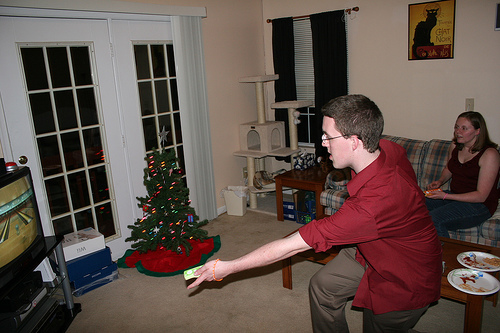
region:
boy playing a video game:
[164, 85, 441, 327]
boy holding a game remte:
[158, 214, 345, 296]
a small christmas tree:
[102, 117, 241, 255]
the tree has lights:
[129, 139, 201, 247]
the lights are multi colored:
[102, 117, 214, 252]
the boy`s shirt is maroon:
[265, 133, 440, 326]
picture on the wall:
[377, 1, 466, 70]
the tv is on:
[2, 166, 97, 308]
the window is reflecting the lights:
[56, 125, 123, 230]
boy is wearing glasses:
[300, 110, 353, 146]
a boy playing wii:
[181, 95, 432, 332]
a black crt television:
[1, 165, 46, 282]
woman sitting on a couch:
[425, 110, 498, 240]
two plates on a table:
[448, 248, 499, 295]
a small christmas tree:
[128, 127, 205, 262]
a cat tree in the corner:
[228, 70, 303, 217]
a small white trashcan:
[223, 183, 249, 215]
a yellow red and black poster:
[405, 0, 455, 61]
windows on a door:
[15, 39, 123, 244]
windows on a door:
[132, 43, 189, 194]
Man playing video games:
[185, 92, 442, 330]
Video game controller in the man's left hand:
[182, 264, 205, 281]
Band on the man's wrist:
[211, 257, 225, 282]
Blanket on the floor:
[118, 228, 220, 276]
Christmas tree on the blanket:
[125, 123, 210, 254]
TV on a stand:
[1, 167, 45, 294]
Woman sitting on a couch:
[422, 109, 499, 240]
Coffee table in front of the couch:
[281, 225, 496, 331]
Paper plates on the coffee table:
[446, 250, 499, 295]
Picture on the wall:
[407, 0, 454, 60]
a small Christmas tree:
[128, 128, 211, 258]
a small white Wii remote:
[179, 260, 223, 286]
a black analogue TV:
[0, 144, 53, 292]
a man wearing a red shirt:
[283, 91, 448, 312]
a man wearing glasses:
[317, 87, 387, 197]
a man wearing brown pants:
[292, 82, 455, 329]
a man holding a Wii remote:
[155, 65, 415, 307]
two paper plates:
[450, 242, 497, 310]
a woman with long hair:
[441, 98, 498, 170]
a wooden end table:
[273, 147, 335, 228]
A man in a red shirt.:
[177, 90, 442, 330]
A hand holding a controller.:
[170, 251, 225, 291]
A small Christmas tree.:
[121, 128, 216, 268]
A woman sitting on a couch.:
[370, 62, 498, 239]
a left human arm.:
[174, 220, 311, 307]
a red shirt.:
[288, 155, 452, 315]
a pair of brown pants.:
[289, 254, 376, 331]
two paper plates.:
[449, 222, 497, 312]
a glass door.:
[5, 25, 131, 255]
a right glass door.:
[125, 30, 210, 237]